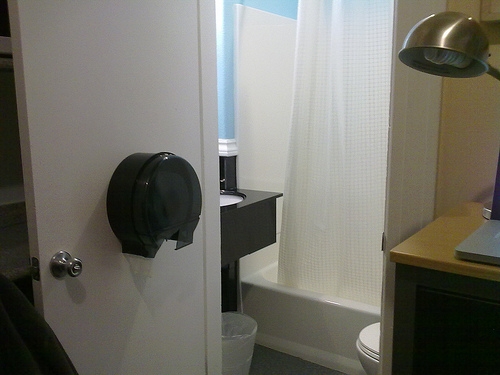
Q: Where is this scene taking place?
A: Hotel room.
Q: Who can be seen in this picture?
A: No one.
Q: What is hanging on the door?
A: Toilet paper.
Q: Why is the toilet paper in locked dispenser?
A: To prevent theft.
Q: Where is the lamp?
A: On the desk.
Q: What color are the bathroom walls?
A: Blue.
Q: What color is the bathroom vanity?
A: Black.